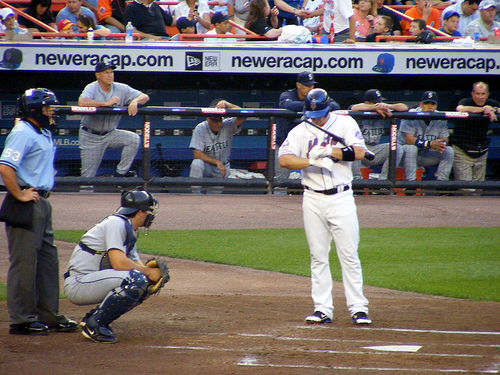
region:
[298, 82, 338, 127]
Ball player wearing a blue helmet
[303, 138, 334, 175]
Player wearing white gloves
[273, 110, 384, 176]
Player holding a baseball bat under his arm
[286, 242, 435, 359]
Player standing next to home plate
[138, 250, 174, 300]
Player wearing a catcher's mitt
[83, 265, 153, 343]
Player wearing knee and shin pads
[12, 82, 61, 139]
umpire wearing a dark helmet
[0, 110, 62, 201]
umpire wearing a light blue jersey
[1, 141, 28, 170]
number 53 on a jersey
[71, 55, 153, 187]
Player standing in baseball dugout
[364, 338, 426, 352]
a white base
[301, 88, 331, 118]
a blue helmet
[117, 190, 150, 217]
a black helmet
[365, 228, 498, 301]
a section of green grass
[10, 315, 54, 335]
a man's black shoe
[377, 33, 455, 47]
a long orange pole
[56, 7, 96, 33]
part of a man's blue shirt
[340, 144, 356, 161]
a black arm band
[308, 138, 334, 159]
a white baseball glove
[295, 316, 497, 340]
a long white line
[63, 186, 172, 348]
Baseball catcher crouching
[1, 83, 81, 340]
Baseball umpire standing behind home plate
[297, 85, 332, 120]
Blue batting helmet on a player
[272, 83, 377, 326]
Met's baseball player at bat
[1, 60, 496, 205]
Baseball dugout during a game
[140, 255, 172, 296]
Baseball catcher's mit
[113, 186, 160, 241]
Baseball catcher mask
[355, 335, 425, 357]
Baseball home plate during a game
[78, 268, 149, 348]
Baseball catcher's shin guards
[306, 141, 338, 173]
Baseball player's batting gloves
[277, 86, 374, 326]
a professional baseball batter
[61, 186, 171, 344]
a professional baseball catcher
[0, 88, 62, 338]
a professional baseball umpire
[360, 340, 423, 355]
the home-plate on the baseball field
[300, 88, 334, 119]
a blue hard helmet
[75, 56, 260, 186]
baseball players in the dugout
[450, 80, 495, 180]
a professional baseball coach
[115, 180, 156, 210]
a blue helmet on the catcher's head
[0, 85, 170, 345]
an umpire standing behind the catcher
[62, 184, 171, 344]
a professional baseball catcher squatting on the ground